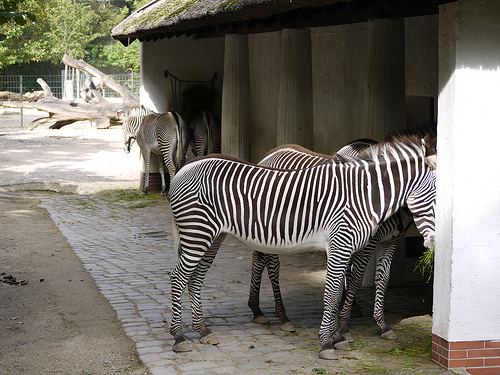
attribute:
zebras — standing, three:
[155, 129, 437, 337]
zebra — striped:
[252, 172, 398, 314]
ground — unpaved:
[6, 190, 211, 347]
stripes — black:
[168, 133, 423, 344]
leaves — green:
[8, 0, 105, 58]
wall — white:
[448, 119, 487, 258]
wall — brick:
[452, 127, 487, 256]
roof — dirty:
[100, 4, 491, 42]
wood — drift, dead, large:
[24, 79, 131, 131]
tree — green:
[18, 10, 111, 67]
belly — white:
[239, 236, 322, 255]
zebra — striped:
[130, 140, 459, 362]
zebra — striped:
[158, 127, 438, 362]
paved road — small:
[1, 192, 133, 374]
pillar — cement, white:
[432, 2, 499, 373]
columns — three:
[213, 14, 410, 160]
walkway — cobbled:
[59, 190, 280, 372]